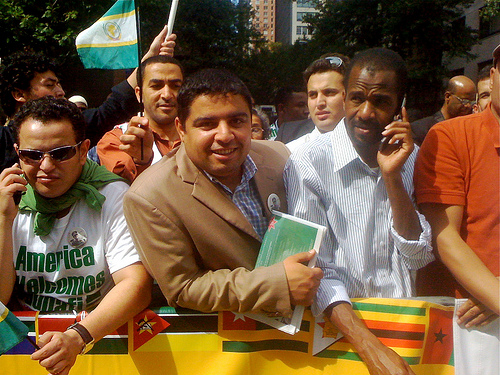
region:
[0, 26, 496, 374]
People are in a group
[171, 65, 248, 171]
The man is smiling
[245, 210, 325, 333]
The paper is green and white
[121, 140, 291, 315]
The jacket is brown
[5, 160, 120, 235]
The scarf is green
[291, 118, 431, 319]
The shirt is white with blue stripes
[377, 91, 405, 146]
The man is holding a phone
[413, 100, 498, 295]
The shirt is orange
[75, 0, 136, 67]
The flag is green white and yellow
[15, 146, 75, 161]
The glasses are dark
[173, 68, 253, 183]
Man with dark brown hair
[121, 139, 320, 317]
Man in a light brown suit jacket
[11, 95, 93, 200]
A mean wearing sun glasses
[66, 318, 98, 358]
Watch with a brown band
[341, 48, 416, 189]
Man talking on a cell phone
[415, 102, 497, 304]
Man wearing an orange shirt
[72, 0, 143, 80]
Green, white and yellow flag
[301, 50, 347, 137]
Man with sun glasses on top of his head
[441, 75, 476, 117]
Man with a bald head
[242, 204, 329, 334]
Man holding a paper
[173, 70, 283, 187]
head of a man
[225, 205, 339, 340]
object in man's hand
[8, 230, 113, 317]
green writing on a shirt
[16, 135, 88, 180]
glasses on man's face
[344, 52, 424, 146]
man talking on a phone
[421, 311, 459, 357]
star on an item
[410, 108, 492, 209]
orange shirt on person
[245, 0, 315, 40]
buildings in the background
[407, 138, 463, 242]
shadow on man's arm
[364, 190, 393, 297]
buttons on the shirt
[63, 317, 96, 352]
brown watch on hand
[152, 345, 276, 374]
yellow color on flag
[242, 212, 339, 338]
newspaper in man's hand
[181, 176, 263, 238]
brown lapel on jacket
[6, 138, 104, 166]
retro pair of sun glasses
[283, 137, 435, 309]
white shirt with blue stripes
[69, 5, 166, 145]
green and white flag on pole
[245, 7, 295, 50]
tall apartment building in the background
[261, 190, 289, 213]
small round white button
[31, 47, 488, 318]
men standing in front of large flag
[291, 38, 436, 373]
man holding a cell phone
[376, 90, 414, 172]
black cell phone on hand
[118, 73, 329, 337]
happy man is smiling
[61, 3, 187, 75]
a green and white flag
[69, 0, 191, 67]
hand holding a flag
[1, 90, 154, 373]
man wears white shirt with green letters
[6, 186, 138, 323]
green letters on white shirt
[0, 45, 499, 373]
people behind a fence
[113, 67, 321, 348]
man wears a brown jacket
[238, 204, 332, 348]
hand holding a newspaper